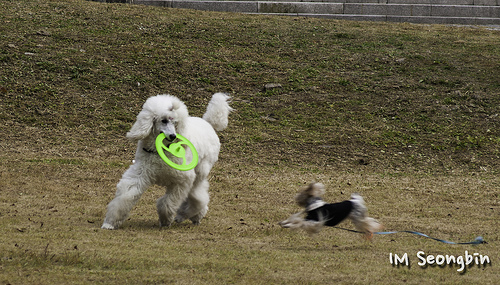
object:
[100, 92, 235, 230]
dog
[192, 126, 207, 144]
color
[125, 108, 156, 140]
ear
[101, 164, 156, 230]
leg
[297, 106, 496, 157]
vegetation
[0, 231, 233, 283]
dirt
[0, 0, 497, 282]
ground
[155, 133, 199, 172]
frisbee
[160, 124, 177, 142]
mouth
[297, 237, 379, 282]
grass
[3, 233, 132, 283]
grass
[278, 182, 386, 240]
dog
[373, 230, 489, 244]
leash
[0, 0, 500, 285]
park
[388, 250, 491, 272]
text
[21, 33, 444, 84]
grass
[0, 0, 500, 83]
hill